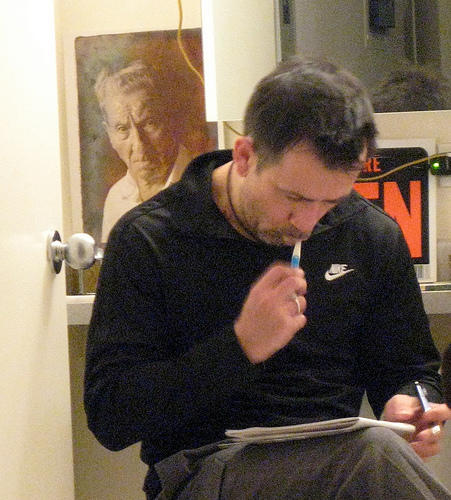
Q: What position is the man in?
A: Sitting.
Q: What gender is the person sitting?
A: Male.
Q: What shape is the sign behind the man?
A: Rectangle.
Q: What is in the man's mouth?
A: A toothbrush.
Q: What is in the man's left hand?
A: A pen.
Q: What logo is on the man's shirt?
A: Nike.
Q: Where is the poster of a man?
A: On the wall.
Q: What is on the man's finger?
A: A ring.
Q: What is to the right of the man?
A: An open door.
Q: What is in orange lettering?
A: An OPEN sign.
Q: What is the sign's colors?
A: Black and orange.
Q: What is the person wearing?
A: A black shirt.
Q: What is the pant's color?
A: Gray.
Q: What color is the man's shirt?
A: Black.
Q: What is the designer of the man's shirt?
A: Nike.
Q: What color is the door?
A: White.